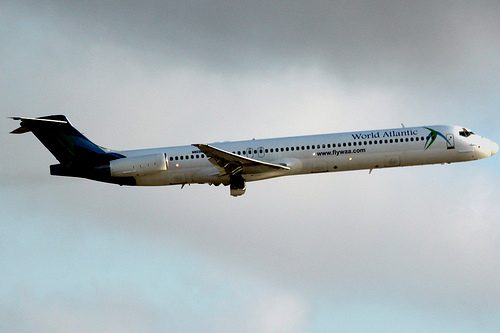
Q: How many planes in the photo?
A: One.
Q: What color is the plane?
A: White.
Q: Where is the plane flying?
A: In the sky.